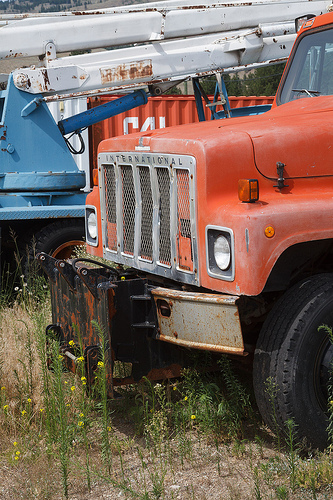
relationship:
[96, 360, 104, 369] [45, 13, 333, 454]
flowers in front of jeep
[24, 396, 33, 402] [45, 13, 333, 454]
flowers in front of jeep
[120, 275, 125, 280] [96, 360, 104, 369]
flowers in front of flowers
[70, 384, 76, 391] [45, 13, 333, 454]
flowers in front of jeep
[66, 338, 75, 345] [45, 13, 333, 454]
flowers in front of jeep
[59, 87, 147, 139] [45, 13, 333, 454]
shock on jeep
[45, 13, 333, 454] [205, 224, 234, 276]
jeep has front headlight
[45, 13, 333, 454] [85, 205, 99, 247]
jeep has front headlight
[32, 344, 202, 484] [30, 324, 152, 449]
weeds on flowers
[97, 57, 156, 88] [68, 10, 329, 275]
rust on truck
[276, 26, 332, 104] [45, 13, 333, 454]
windshield on jeep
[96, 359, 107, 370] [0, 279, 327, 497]
flower on weeds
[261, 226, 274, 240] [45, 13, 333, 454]
light on jeep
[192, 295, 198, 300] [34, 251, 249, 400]
spots on bumper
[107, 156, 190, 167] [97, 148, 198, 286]
letters on front grill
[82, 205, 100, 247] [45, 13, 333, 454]
front headlight on jeep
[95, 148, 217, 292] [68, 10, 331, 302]
window on jeep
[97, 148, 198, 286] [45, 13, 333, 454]
front grill on jeep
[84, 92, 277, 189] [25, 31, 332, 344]
trailer behind truck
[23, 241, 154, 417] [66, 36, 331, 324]
machinery in front of truck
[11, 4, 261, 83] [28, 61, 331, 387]
machinery on truck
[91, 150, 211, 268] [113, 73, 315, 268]
grate on truck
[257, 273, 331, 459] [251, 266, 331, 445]
jeepwheel of jeepwheel